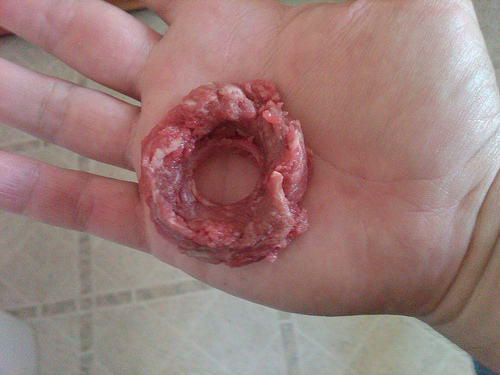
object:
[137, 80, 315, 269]
doughnut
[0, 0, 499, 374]
person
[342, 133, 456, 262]
flesh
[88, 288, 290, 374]
tile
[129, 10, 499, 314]
palm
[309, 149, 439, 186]
arched line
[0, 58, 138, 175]
finger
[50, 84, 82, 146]
lines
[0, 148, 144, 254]
finger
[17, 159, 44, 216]
lines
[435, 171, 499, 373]
wrist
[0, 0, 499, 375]
floor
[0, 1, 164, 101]
finger